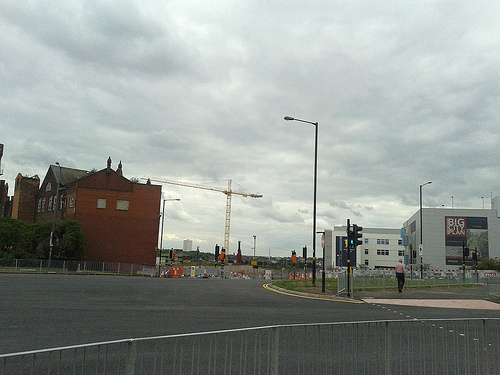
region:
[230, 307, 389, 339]
edge of silver fence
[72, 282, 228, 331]
gray color on street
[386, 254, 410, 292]
man walking on the sidewalk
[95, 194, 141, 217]
white blinds in the window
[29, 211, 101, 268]
green trees growing on side of house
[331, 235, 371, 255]
green light in traffic signal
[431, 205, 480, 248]
big sign on the side of building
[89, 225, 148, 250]
red color on the wall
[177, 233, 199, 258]
tall building in the distance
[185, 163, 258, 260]
large construction crane behind houses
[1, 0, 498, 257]
a sky filled with clouds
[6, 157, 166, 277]
an old brick building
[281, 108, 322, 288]
a light pole on the corner of the street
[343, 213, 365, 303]
a traffic light that has turned green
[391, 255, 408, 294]
a man walking in the street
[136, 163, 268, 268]
a yellow construction crane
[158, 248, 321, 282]
a construction zone at the end of the street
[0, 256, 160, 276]
a metal fence on the side of the street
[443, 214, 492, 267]
an advertisement on the side of the building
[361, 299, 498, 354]
a white dotted line painted on the street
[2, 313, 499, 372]
grey metal fence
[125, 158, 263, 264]
tall t shaped construction equipment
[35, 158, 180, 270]
tall red building next to construction site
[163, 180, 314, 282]
construction site near road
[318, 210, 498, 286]
two white buildings with banner on the side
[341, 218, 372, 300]
two traffic signals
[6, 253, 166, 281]
fence in front of red building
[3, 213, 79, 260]
green trees in front of red buildings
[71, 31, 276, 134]
grey clouds in the sky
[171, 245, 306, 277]
construction site signs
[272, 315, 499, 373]
silver metal railings on side of street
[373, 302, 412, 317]
white dotted lines on the street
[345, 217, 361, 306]
black traffic signal on the street corner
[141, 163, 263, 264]
tall yellow building cran in the background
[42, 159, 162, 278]
red brick building with two white squares on the side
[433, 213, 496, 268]
advertisement on the side of building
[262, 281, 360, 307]
yellow line on the corner of the street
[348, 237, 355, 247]
green light of traffic sign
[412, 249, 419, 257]
red light on traffic sign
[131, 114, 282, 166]
sky is covered with grey clouds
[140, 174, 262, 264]
large orange crane for building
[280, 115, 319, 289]
tall black light pole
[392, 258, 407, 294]
white haired man walking away from the camera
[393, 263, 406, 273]
pink shirt on a 'real man'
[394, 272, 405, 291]
men's black chinos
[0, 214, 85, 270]
high bushes hiding the backyard of the apt. complex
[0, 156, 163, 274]
reddish brown apartment building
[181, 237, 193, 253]
tall skyscraper in the far background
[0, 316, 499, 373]
metal gate blocking whoever from the road or from the land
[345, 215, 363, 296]
stop and go lights on green